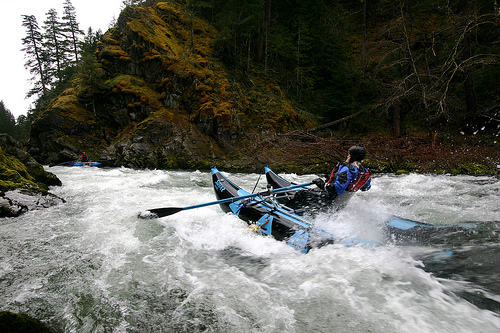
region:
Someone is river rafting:
[105, 139, 412, 314]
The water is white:
[131, 225, 447, 310]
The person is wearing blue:
[312, 138, 399, 234]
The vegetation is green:
[95, 67, 355, 139]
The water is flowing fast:
[72, 195, 378, 305]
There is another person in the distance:
[35, 121, 166, 207]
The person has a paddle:
[98, 171, 363, 266]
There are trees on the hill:
[375, 68, 492, 198]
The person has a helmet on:
[346, 140, 392, 215]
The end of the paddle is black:
[125, 195, 210, 247]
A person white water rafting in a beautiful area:
[0, 14, 492, 307]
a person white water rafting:
[199, 137, 455, 267]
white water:
[59, 198, 326, 312]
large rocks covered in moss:
[55, 49, 242, 170]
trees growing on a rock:
[222, 0, 485, 121]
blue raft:
[211, 158, 464, 279]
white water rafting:
[114, 143, 469, 265]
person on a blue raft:
[203, 143, 471, 286]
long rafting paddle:
[137, 173, 322, 231]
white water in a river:
[16, 183, 495, 327]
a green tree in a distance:
[16, 14, 56, 100]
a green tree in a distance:
[43, 5, 67, 77]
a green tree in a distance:
[62, 3, 86, 59]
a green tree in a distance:
[0, 100, 21, 144]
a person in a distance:
[64, 144, 103, 175]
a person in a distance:
[290, 137, 369, 212]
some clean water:
[0, 157, 483, 330]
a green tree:
[75, 27, 95, 78]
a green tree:
[250, 8, 273, 80]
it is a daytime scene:
[0, 0, 499, 332]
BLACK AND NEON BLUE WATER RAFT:
[121, 122, 442, 303]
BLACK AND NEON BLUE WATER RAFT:
[130, 92, 395, 265]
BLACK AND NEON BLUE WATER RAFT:
[220, 144, 470, 326]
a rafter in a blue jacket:
[320, 139, 373, 206]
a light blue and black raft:
[209, 162, 332, 249]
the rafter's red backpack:
[350, 169, 370, 194]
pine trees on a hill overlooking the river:
[17, 3, 88, 80]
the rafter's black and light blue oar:
[135, 174, 307, 225]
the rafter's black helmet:
[344, 144, 369, 161]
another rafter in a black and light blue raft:
[71, 148, 102, 169]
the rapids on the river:
[176, 213, 240, 323]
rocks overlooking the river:
[122, 3, 239, 163]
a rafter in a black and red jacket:
[76, 148, 92, 161]